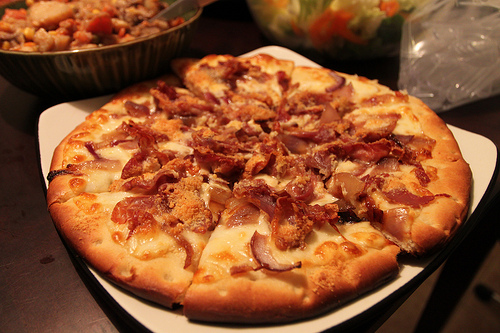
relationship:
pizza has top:
[48, 51, 476, 329] [110, 76, 432, 239]